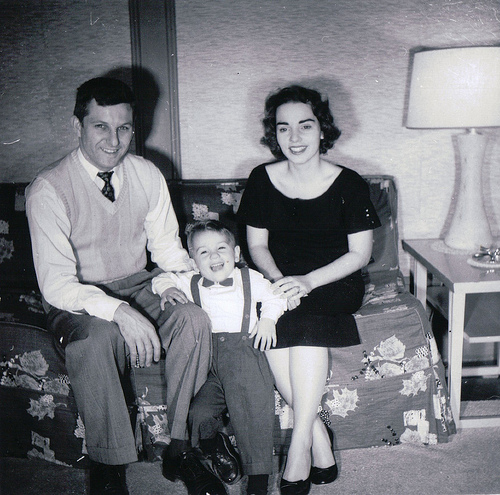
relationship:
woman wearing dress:
[223, 78, 412, 445] [239, 159, 381, 346]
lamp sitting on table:
[406, 45, 500, 252] [401, 236, 498, 428]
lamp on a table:
[401, 34, 498, 260] [386, 222, 495, 390]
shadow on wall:
[110, 65, 178, 177] [6, 0, 475, 191]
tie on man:
[97, 171, 117, 200] [28, 78, 186, 493]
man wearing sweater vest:
[37, 78, 213, 480] [35, 145, 161, 283]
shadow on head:
[246, 75, 363, 142] [260, 86, 341, 161]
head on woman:
[260, 86, 341, 161] [234, 84, 383, 495]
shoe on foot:
[283, 478, 310, 492] [285, 451, 308, 479]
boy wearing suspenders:
[151, 225, 288, 493] [189, 264, 251, 335]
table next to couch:
[396, 229, 498, 424] [3, 171, 453, 430]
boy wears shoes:
[151, 220, 288, 495] [83, 442, 254, 492]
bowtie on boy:
[191, 271, 241, 297] [139, 188, 281, 356]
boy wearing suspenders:
[151, 225, 288, 493] [185, 264, 255, 333]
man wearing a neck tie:
[37, 78, 213, 480] [85, 162, 125, 199]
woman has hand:
[234, 84, 383, 495] [270, 267, 312, 297]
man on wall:
[37, 78, 213, 480] [162, 4, 493, 394]